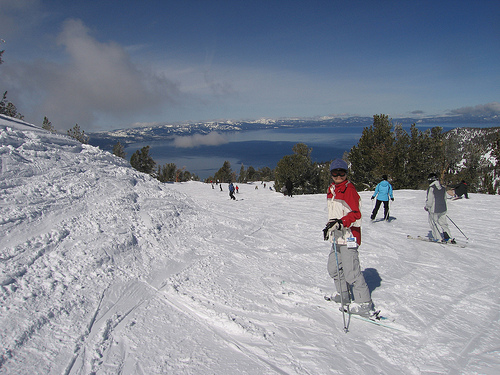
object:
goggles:
[319, 164, 356, 182]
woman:
[370, 174, 394, 224]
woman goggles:
[316, 161, 356, 183]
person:
[366, 171, 400, 222]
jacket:
[371, 184, 392, 203]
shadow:
[356, 264, 386, 294]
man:
[304, 143, 395, 337]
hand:
[316, 217, 352, 252]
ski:
[324, 289, 401, 329]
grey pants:
[319, 237, 375, 310]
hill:
[8, 91, 488, 361]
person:
[322, 157, 376, 317]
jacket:
[325, 178, 362, 245]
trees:
[330, 106, 498, 190]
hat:
[326, 157, 347, 172]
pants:
[326, 241, 371, 305]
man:
[416, 166, 456, 245]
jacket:
[423, 183, 444, 215]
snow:
[4, 101, 498, 371]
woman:
[322, 158, 377, 323]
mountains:
[88, 115, 492, 140]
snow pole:
[445, 212, 468, 242]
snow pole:
[426, 209, 447, 244]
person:
[424, 172, 454, 244]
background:
[91, 108, 497, 152]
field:
[154, 177, 498, 373]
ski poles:
[328, 233, 350, 336]